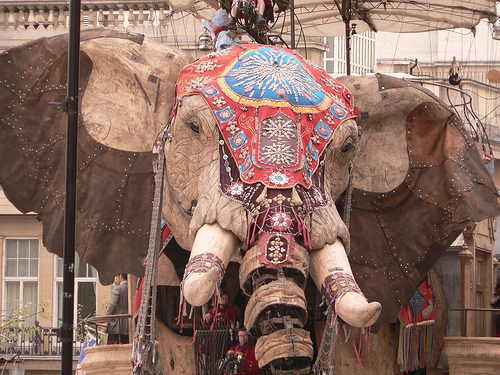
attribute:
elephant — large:
[1, 30, 499, 374]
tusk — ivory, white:
[181, 224, 241, 307]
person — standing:
[191, 8, 245, 51]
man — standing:
[103, 271, 131, 346]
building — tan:
[0, 0, 500, 374]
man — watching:
[204, 293, 244, 329]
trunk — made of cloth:
[237, 235, 316, 374]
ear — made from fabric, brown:
[1, 27, 195, 288]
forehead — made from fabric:
[178, 43, 363, 116]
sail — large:
[271, 0, 499, 36]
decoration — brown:
[319, 271, 367, 310]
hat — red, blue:
[177, 42, 363, 191]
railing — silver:
[448, 305, 499, 314]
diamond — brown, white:
[274, 193, 289, 208]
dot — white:
[4, 48, 13, 59]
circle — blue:
[226, 48, 325, 108]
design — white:
[223, 49, 324, 104]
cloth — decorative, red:
[177, 43, 364, 187]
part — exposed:
[262, 312, 307, 333]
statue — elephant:
[1, 26, 497, 373]